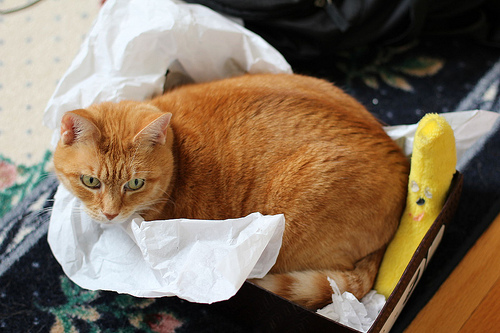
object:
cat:
[52, 70, 407, 311]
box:
[159, 68, 464, 333]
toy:
[373, 112, 459, 303]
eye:
[122, 176, 148, 192]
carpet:
[0, 1, 499, 333]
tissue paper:
[38, 0, 500, 333]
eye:
[79, 172, 101, 191]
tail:
[249, 248, 384, 309]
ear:
[132, 112, 174, 147]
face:
[406, 181, 435, 223]